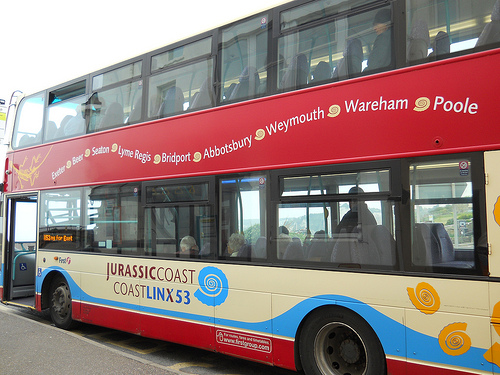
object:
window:
[410, 181, 475, 199]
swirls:
[407, 282, 440, 314]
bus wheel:
[49, 281, 78, 330]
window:
[414, 202, 475, 250]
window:
[238, 190, 261, 246]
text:
[106, 263, 109, 281]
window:
[222, 15, 269, 44]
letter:
[345, 99, 360, 113]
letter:
[359, 102, 365, 112]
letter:
[366, 101, 371, 111]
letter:
[371, 101, 378, 111]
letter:
[379, 96, 387, 111]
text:
[468, 103, 478, 115]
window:
[406, 0, 500, 63]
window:
[44, 94, 86, 141]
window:
[148, 58, 212, 118]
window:
[219, 30, 268, 104]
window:
[277, 4, 392, 90]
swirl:
[194, 266, 229, 307]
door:
[3, 193, 37, 308]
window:
[145, 182, 210, 202]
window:
[277, 189, 332, 239]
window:
[151, 35, 212, 71]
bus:
[0, 0, 500, 375]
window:
[93, 60, 144, 92]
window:
[280, 0, 381, 31]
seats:
[431, 223, 475, 268]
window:
[83, 186, 139, 252]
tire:
[300, 306, 388, 374]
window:
[88, 79, 144, 131]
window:
[337, 183, 383, 226]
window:
[13, 97, 97, 148]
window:
[427, 38, 480, 57]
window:
[7, 199, 101, 242]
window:
[218, 176, 267, 260]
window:
[277, 170, 391, 197]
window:
[408, 160, 475, 269]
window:
[145, 205, 212, 260]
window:
[39, 189, 81, 251]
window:
[277, 200, 397, 266]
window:
[48, 79, 86, 105]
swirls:
[439, 322, 472, 356]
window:
[12, 93, 45, 150]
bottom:
[71, 299, 499, 374]